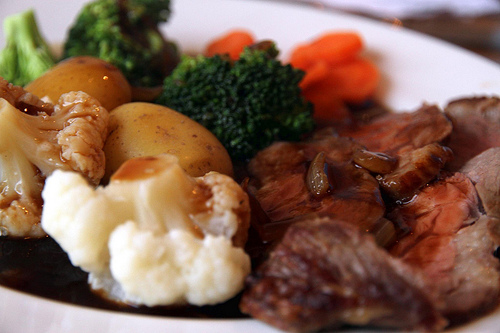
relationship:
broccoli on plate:
[164, 36, 311, 159] [1, 1, 496, 329]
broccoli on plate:
[60, 1, 180, 91] [1, 1, 496, 329]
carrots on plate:
[205, 27, 381, 129] [394, 28, 455, 72]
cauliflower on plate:
[45, 156, 254, 313] [1, 1, 496, 329]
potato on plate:
[17, 51, 128, 117] [1, 1, 496, 329]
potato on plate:
[102, 98, 234, 185] [1, 1, 496, 329]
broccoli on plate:
[0, 8, 60, 89] [1, 1, 496, 329]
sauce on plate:
[4, 235, 181, 308] [1, 1, 496, 329]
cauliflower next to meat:
[37, 149, 256, 313] [327, 130, 487, 268]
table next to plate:
[423, 7, 499, 43] [1, 1, 496, 329]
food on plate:
[6, 1, 495, 331] [214, 9, 437, 46]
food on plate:
[6, 1, 495, 331] [1, 1, 496, 329]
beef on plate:
[254, 214, 452, 330] [1, 1, 496, 329]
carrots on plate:
[201, 20, 373, 112] [1, 1, 496, 329]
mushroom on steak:
[350, 144, 397, 176] [263, 139, 394, 226]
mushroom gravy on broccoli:
[116, 151, 171, 185] [164, 36, 311, 159]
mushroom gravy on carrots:
[116, 151, 171, 185] [283, 25, 381, 129]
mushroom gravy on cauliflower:
[116, 151, 171, 185] [37, 149, 256, 313]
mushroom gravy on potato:
[116, 151, 171, 185] [102, 98, 234, 185]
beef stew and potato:
[239, 97, 499, 331] [17, 51, 128, 117]